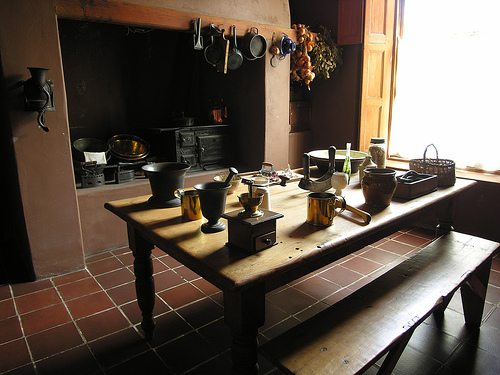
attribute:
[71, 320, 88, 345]
grout — white 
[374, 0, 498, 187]
window — large , bright 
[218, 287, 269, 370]
leg — wooden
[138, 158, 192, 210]
small/black bucket — small and black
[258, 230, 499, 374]
wooden bench — brown and wooden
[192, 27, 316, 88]
pan — black 